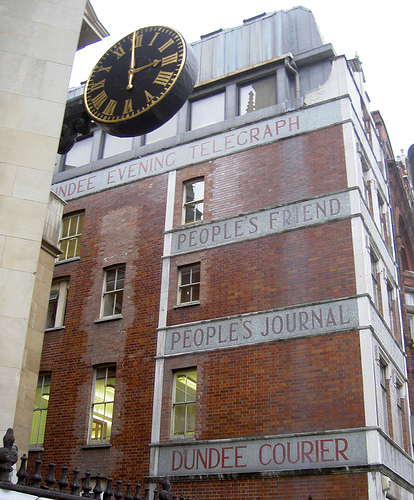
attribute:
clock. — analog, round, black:
[74, 22, 209, 143]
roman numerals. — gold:
[154, 39, 186, 88]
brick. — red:
[262, 156, 333, 183]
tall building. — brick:
[215, 2, 413, 498]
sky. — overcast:
[371, 9, 414, 25]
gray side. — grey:
[343, 63, 373, 117]